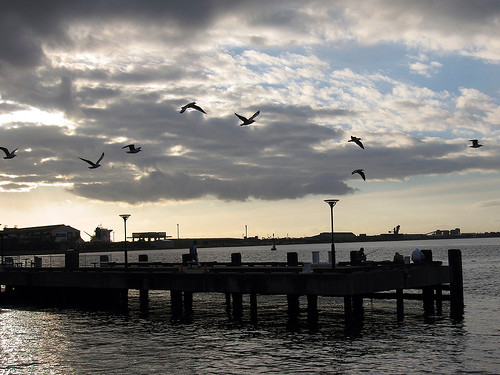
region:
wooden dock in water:
[10, 251, 468, 336]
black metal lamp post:
[328, 205, 334, 267]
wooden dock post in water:
[350, 253, 365, 339]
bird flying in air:
[236, 112, 260, 127]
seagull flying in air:
[349, 135, 364, 150]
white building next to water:
[3, 225, 78, 247]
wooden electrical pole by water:
[176, 223, 181, 242]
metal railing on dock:
[23, 255, 185, 269]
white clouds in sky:
[214, 50, 497, 135]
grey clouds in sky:
[3, 95, 498, 197]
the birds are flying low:
[0, 96, 487, 183]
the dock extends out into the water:
[1, 193, 468, 332]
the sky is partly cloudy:
[4, 3, 496, 223]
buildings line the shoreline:
[0, 219, 492, 257]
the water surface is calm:
[1, 233, 498, 373]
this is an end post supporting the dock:
[445, 246, 467, 321]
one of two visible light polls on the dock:
[322, 195, 342, 273]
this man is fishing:
[353, 241, 380, 262]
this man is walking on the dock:
[185, 236, 202, 268]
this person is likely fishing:
[409, 244, 426, 267]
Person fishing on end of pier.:
[341, 228, 397, 295]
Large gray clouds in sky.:
[64, 53, 334, 208]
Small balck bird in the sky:
[341, 124, 373, 159]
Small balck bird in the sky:
[345, 159, 370, 185]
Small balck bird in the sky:
[453, 113, 484, 165]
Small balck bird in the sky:
[230, 97, 272, 137]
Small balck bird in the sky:
[172, 95, 228, 130]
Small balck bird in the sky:
[109, 132, 158, 158]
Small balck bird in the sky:
[65, 141, 109, 179]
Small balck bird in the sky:
[0, 133, 28, 177]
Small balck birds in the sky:
[1, 111, 147, 198]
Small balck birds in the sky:
[157, 87, 281, 152]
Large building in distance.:
[26, 210, 97, 252]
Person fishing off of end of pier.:
[338, 218, 388, 282]